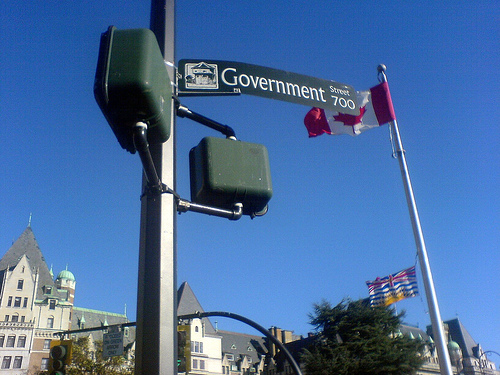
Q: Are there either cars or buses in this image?
A: No, there are no cars or buses.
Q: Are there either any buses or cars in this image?
A: No, there are no cars or buses.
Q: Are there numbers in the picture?
A: Yes, there are numbers.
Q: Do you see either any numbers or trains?
A: Yes, there are numbers.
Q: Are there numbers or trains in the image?
A: Yes, there are numbers.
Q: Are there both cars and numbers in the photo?
A: No, there are numbers but no cars.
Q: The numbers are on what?
A: The numbers are on the sign.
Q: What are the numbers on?
A: The numbers are on the sign.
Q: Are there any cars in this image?
A: No, there are no cars.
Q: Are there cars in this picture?
A: No, there are no cars.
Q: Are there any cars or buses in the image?
A: No, there are no cars or buses.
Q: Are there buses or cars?
A: No, there are no cars or buses.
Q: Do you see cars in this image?
A: No, there are no cars.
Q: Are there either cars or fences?
A: No, there are no cars or fences.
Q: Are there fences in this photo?
A: No, there are no fences.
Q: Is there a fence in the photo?
A: No, there are no fences.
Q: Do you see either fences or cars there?
A: No, there are no fences or cars.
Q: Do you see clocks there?
A: No, there are no clocks.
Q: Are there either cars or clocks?
A: No, there are no clocks or cars.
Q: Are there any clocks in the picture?
A: No, there are no clocks.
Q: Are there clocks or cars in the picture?
A: No, there are no clocks or cars.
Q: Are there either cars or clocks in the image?
A: No, there are no clocks or cars.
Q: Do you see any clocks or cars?
A: No, there are no clocks or cars.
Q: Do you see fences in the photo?
A: No, there are no fences.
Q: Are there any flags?
A: Yes, there is a flag.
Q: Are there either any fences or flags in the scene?
A: Yes, there is a flag.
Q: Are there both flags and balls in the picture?
A: No, there is a flag but no balls.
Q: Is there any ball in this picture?
A: No, there are no balls.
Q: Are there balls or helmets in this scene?
A: No, there are no balls or helmets.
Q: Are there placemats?
A: No, there are no placemats.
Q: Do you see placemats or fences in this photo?
A: No, there are no placemats or fences.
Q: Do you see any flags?
A: Yes, there is a flag.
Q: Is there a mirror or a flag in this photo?
A: Yes, there is a flag.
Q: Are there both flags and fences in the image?
A: No, there is a flag but no fences.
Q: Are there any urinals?
A: No, there are no urinals.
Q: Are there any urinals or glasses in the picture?
A: No, there are no urinals or glasses.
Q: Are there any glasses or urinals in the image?
A: No, there are no urinals or glasses.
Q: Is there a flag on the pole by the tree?
A: Yes, there is a flag on the pole.